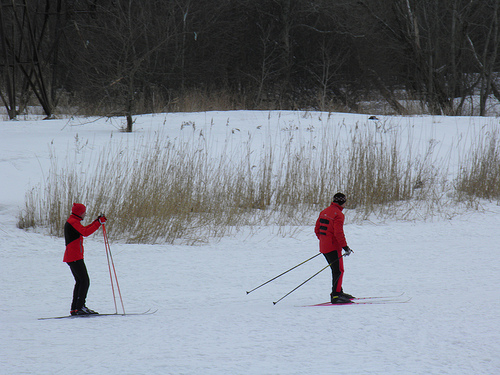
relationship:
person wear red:
[59, 200, 108, 318] [69, 199, 86, 263]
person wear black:
[59, 200, 108, 318] [78, 267, 83, 301]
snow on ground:
[207, 305, 486, 374] [166, 244, 259, 278]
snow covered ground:
[207, 305, 486, 374] [166, 244, 259, 278]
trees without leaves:
[59, 4, 480, 107] [254, 21, 309, 98]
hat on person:
[68, 199, 87, 220] [59, 204, 108, 317]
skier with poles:
[59, 204, 108, 317] [93, 211, 125, 320]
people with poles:
[310, 187, 360, 308] [243, 247, 354, 307]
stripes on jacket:
[315, 217, 334, 238] [309, 201, 358, 257]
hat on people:
[329, 190, 351, 207] [310, 187, 360, 308]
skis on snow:
[33, 308, 164, 329] [207, 305, 486, 374]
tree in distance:
[97, 14, 157, 117] [19, 23, 425, 126]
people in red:
[310, 187, 360, 308] [69, 199, 86, 263]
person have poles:
[59, 200, 108, 318] [93, 211, 125, 320]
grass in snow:
[103, 129, 399, 234] [207, 305, 486, 374]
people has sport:
[310, 187, 360, 308] [25, 288, 474, 373]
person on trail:
[59, 200, 108, 318] [20, 294, 499, 317]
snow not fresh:
[207, 305, 486, 374] [442, 315, 492, 374]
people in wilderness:
[310, 187, 360, 308] [12, 59, 491, 229]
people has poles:
[310, 187, 360, 308] [93, 211, 125, 320]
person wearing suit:
[59, 204, 108, 317] [55, 202, 92, 312]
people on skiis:
[310, 187, 360, 308] [274, 296, 421, 306]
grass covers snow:
[103, 129, 399, 234] [207, 305, 486, 374]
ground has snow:
[166, 244, 259, 278] [207, 305, 486, 374]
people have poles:
[45, 187, 373, 273] [93, 211, 125, 320]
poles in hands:
[93, 211, 125, 320] [95, 214, 112, 225]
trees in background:
[59, 4, 480, 107] [12, 10, 475, 175]